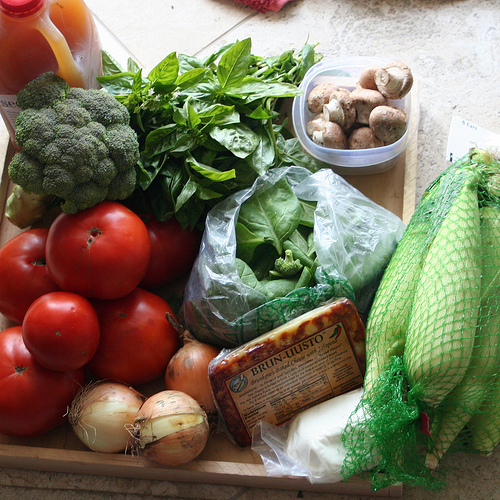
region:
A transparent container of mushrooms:
[296, 55, 416, 170]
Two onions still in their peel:
[65, 374, 210, 464]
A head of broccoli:
[5, 73, 135, 220]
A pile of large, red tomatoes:
[4, 205, 180, 402]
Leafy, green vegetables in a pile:
[135, 55, 287, 196]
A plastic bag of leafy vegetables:
[192, 175, 374, 320]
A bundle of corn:
[370, 163, 498, 470]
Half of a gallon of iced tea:
[3, 1, 102, 122]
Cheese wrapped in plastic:
[208, 298, 379, 453]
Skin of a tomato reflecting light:
[100, 203, 132, 237]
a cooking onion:
[70, 385, 140, 440]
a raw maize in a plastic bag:
[425, 205, 475, 388]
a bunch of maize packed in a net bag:
[355, 161, 490, 391]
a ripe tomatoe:
[17, 295, 102, 365]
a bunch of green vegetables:
[131, 75, 296, 177]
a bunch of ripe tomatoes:
[6, 221, 161, 376]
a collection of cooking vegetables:
[25, 87, 480, 475]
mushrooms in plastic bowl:
[293, 56, 413, 175]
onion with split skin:
[130, 387, 207, 463]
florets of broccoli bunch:
[6, 74, 136, 223]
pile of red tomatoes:
[0, 202, 187, 429]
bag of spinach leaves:
[183, 165, 401, 335]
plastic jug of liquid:
[2, 5, 100, 132]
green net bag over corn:
[361, 150, 495, 481]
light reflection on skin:
[104, 206, 125, 229]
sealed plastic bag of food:
[207, 297, 367, 447]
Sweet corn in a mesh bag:
[372, 153, 499, 485]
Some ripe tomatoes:
[2, 214, 164, 378]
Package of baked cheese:
[204, 291, 378, 436]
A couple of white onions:
[68, 378, 208, 465]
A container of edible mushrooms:
[294, 56, 427, 164]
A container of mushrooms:
[295, 53, 416, 159]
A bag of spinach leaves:
[206, 176, 396, 301]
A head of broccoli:
[4, 68, 135, 217]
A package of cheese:
[206, 296, 368, 452]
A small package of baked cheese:
[207, 294, 375, 444]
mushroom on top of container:
[375, 61, 415, 98]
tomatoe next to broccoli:
[43, 197, 160, 297]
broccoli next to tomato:
[6, 81, 148, 211]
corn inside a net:
[339, 152, 498, 491]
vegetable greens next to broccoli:
[102, 31, 315, 200]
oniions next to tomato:
[67, 377, 141, 459]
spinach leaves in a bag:
[173, 165, 401, 342]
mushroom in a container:
[323, 90, 356, 125]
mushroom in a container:
[310, 117, 342, 147]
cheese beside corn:
[253, 386, 392, 481]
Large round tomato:
[43, 201, 150, 297]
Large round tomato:
[28, 295, 99, 364]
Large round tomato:
[2, 229, 67, 318]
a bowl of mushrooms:
[295, 60, 413, 172]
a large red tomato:
[40, 204, 155, 298]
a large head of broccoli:
[10, 73, 141, 213]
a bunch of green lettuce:
[105, 33, 317, 224]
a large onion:
[132, 388, 209, 467]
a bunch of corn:
[335, 134, 499, 490]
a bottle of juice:
[0, 0, 104, 154]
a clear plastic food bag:
[301, 165, 401, 292]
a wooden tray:
[0, 433, 413, 493]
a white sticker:
[2, 95, 22, 134]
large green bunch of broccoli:
[11, 71, 138, 215]